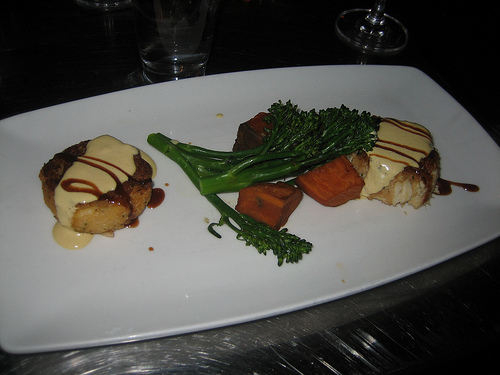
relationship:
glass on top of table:
[139, 0, 208, 83] [8, 24, 489, 370]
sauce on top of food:
[39, 124, 151, 228] [37, 134, 158, 234]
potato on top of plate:
[238, 181, 303, 230] [11, 63, 490, 349]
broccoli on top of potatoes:
[190, 79, 368, 185] [236, 165, 365, 226]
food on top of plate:
[45, 142, 167, 248] [11, 63, 490, 349]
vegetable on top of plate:
[164, 92, 374, 257] [11, 63, 490, 349]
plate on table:
[11, 63, 490, 349] [8, 24, 489, 370]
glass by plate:
[344, 0, 395, 61] [11, 63, 490, 349]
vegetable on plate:
[198, 98, 382, 197] [11, 63, 490, 349]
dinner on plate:
[38, 100, 447, 266] [11, 63, 490, 349]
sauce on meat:
[50, 134, 157, 254] [38, 136, 170, 246]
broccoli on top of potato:
[147, 95, 377, 269] [235, 182, 303, 231]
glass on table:
[139, 0, 208, 83] [8, 24, 489, 370]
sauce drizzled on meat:
[50, 134, 157, 251] [39, 138, 157, 233]